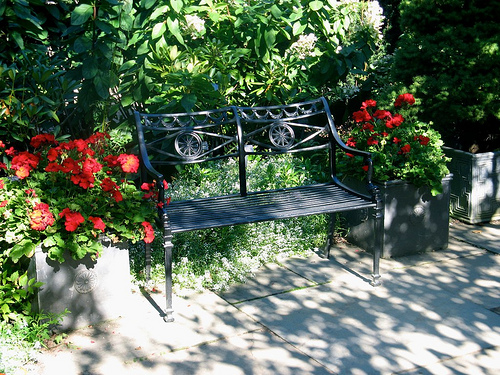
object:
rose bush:
[343, 93, 452, 181]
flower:
[395, 93, 415, 106]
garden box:
[339, 176, 448, 260]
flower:
[419, 135, 430, 145]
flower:
[65, 212, 85, 232]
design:
[74, 269, 98, 294]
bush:
[135, 150, 330, 261]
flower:
[203, 193, 209, 198]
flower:
[221, 257, 228, 263]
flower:
[262, 254, 268, 258]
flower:
[276, 224, 281, 228]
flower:
[117, 153, 140, 173]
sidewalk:
[0, 220, 500, 375]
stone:
[227, 278, 500, 375]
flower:
[15, 166, 29, 179]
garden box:
[26, 244, 131, 329]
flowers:
[184, 15, 205, 32]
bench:
[133, 97, 384, 323]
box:
[340, 174, 454, 259]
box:
[436, 145, 499, 223]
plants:
[144, 69, 229, 112]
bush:
[0, 132, 171, 263]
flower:
[30, 202, 55, 230]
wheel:
[175, 132, 203, 157]